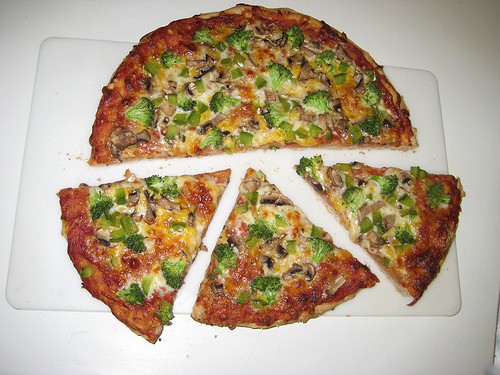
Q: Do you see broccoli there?
A: Yes, there is broccoli.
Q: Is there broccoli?
A: Yes, there is broccoli.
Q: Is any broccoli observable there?
A: Yes, there is broccoli.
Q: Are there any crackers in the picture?
A: No, there are no crackers.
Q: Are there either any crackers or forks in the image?
A: No, there are no crackers or forks.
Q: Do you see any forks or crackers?
A: No, there are no crackers or forks.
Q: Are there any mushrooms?
A: Yes, there are mushrooms.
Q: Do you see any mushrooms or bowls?
A: Yes, there are mushrooms.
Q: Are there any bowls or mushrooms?
A: Yes, there are mushrooms.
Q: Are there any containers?
A: No, there are no containers.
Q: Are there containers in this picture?
A: No, there are no containers.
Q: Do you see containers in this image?
A: No, there are no containers.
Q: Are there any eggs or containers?
A: No, there are no containers or eggs.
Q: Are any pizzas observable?
A: Yes, there is a pizza.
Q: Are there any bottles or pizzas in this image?
A: Yes, there is a pizza.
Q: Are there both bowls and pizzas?
A: No, there is a pizza but no bowls.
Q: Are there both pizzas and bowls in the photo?
A: No, there is a pizza but no bowls.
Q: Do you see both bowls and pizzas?
A: No, there is a pizza but no bowls.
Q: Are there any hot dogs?
A: No, there are no hot dogs.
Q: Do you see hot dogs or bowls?
A: No, there are no hot dogs or bowls.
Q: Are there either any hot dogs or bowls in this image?
A: No, there are no hot dogs or bowls.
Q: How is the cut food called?
A: The food is a pizza.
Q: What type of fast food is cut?
A: The fast food is a pizza.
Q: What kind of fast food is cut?
A: The fast food is a pizza.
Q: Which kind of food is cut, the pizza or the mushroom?
A: The pizza is cut.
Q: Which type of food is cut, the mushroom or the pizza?
A: The pizza is cut.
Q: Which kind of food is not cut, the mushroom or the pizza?
A: The mushroom is not cut.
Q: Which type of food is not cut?
A: The food is a mushroom.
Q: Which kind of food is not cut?
A: The food is a mushroom.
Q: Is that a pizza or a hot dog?
A: That is a pizza.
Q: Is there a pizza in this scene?
A: Yes, there is a pizza.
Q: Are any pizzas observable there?
A: Yes, there is a pizza.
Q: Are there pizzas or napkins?
A: Yes, there is a pizza.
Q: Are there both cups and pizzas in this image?
A: No, there is a pizza but no cups.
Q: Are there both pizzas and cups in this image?
A: No, there is a pizza but no cups.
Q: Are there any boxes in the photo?
A: No, there are no boxes.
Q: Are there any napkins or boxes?
A: No, there are no boxes or napkins.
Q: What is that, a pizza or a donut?
A: That is a pizza.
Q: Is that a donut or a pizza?
A: That is a pizza.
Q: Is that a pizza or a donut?
A: That is a pizza.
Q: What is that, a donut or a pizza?
A: That is a pizza.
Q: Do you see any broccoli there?
A: Yes, there is broccoli.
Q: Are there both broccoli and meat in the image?
A: No, there is broccoli but no meat.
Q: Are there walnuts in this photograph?
A: No, there are no walnuts.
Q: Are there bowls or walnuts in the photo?
A: No, there are no walnuts or bowls.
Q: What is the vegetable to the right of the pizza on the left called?
A: The vegetable is broccoli.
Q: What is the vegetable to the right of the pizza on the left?
A: The vegetable is broccoli.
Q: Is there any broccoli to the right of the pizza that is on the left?
A: Yes, there is broccoli to the right of the pizza.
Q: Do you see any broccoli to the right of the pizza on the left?
A: Yes, there is broccoli to the right of the pizza.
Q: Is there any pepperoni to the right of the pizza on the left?
A: No, there is broccoli to the right of the pizza.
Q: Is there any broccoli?
A: Yes, there is broccoli.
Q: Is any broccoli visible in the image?
A: Yes, there is broccoli.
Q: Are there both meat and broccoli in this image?
A: No, there is broccoli but no meat.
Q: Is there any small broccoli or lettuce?
A: Yes, there is small broccoli.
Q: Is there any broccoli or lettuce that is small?
A: Yes, the broccoli is small.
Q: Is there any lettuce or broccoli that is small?
A: Yes, the broccoli is small.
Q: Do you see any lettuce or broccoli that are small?
A: Yes, the broccoli is small.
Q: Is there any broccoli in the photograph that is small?
A: Yes, there is small broccoli.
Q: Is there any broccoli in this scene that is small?
A: Yes, there is broccoli that is small.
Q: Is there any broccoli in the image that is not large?
A: Yes, there is small broccoli.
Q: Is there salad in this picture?
A: No, there is no salad.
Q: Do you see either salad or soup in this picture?
A: No, there are no salad or soup.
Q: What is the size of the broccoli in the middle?
A: The broccoli is small.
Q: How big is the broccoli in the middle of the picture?
A: The broccoli is small.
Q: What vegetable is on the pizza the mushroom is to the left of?
A: The vegetable is broccoli.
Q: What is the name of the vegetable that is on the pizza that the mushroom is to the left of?
A: The vegetable is broccoli.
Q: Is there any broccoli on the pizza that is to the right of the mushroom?
A: Yes, there is broccoli on the pizza.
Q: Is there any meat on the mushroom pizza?
A: No, there is broccoli on the pizza.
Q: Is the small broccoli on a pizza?
A: Yes, the broccoli is on a pizza.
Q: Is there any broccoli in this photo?
A: Yes, there is broccoli.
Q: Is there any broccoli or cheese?
A: Yes, there is broccoli.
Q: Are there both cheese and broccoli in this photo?
A: Yes, there are both broccoli and cheese.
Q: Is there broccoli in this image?
A: Yes, there is broccoli.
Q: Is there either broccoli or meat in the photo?
A: Yes, there is broccoli.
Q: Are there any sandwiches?
A: No, there are no sandwiches.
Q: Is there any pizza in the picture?
A: Yes, there is a pizza.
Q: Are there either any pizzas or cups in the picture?
A: Yes, there is a pizza.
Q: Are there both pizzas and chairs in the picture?
A: No, there is a pizza but no chairs.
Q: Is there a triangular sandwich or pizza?
A: Yes, there is a triangular pizza.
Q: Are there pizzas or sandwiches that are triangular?
A: Yes, the pizza is triangular.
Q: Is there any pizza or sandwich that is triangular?
A: Yes, the pizza is triangular.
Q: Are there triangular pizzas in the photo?
A: Yes, there is a triangular pizza.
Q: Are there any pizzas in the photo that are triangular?
A: Yes, there is a pizza that is triangular.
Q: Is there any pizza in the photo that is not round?
A: Yes, there is a triangular pizza.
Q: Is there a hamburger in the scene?
A: No, there are no hamburgers.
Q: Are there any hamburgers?
A: No, there are no hamburgers.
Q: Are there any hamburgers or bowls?
A: No, there are no hamburgers or bowls.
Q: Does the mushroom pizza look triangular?
A: Yes, the pizza is triangular.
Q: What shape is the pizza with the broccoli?
A: The pizza is triangular.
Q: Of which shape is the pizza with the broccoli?
A: The pizza is triangular.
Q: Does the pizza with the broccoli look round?
A: No, the pizza is triangular.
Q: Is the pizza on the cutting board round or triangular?
A: The pizza is triangular.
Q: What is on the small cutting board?
A: The pizza is on the cutting board.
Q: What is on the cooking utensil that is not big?
A: The pizza is on the cutting board.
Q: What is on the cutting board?
A: The pizza is on the cutting board.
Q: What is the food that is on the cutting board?
A: The food is a pizza.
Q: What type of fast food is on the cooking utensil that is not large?
A: The food is a pizza.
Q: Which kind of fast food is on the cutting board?
A: The food is a pizza.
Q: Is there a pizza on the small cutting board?
A: Yes, there is a pizza on the cutting board.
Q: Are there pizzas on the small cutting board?
A: Yes, there is a pizza on the cutting board.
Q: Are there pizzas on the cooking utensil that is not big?
A: Yes, there is a pizza on the cutting board.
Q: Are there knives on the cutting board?
A: No, there is a pizza on the cutting board.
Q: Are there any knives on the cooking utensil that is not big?
A: No, there is a pizza on the cutting board.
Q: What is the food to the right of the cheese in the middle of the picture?
A: The food is a pizza.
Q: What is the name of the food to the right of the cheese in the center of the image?
A: The food is a pizza.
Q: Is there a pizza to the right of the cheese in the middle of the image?
A: Yes, there is a pizza to the right of the cheese.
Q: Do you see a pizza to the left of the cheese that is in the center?
A: No, the pizza is to the right of the cheese.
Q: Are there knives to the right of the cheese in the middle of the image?
A: No, there is a pizza to the right of the cheese.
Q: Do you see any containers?
A: No, there are no containers.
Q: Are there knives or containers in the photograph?
A: No, there are no containers or knives.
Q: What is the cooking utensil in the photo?
A: The cooking utensil is a cutting board.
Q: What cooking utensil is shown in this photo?
A: The cooking utensil is a cutting board.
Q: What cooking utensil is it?
A: The cooking utensil is a cutting board.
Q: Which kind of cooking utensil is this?
A: This is a cutting board.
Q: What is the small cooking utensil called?
A: The cooking utensil is a cutting board.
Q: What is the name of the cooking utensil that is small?
A: The cooking utensil is a cutting board.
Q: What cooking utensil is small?
A: The cooking utensil is a cutting board.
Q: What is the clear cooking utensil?
A: The cooking utensil is a cutting board.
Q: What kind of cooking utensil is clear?
A: The cooking utensil is a cutting board.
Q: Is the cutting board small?
A: Yes, the cutting board is small.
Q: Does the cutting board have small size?
A: Yes, the cutting board is small.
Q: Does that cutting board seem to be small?
A: Yes, the cutting board is small.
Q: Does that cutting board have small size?
A: Yes, the cutting board is small.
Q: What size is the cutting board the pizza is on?
A: The cutting board is small.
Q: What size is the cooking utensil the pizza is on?
A: The cutting board is small.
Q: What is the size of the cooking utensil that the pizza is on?
A: The cutting board is small.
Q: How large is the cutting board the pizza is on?
A: The cutting board is small.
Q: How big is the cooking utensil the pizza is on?
A: The cutting board is small.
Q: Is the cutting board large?
A: No, the cutting board is small.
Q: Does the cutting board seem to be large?
A: No, the cutting board is small.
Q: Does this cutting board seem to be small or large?
A: The cutting board is small.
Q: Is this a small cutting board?
A: Yes, this is a small cutting board.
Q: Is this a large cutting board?
A: No, this is a small cutting board.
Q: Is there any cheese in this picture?
A: Yes, there is cheese.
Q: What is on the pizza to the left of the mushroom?
A: The cheese is on the pizza.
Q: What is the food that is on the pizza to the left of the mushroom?
A: The food is cheese.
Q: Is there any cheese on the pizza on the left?
A: Yes, there is cheese on the pizza.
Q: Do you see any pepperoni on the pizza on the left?
A: No, there is cheese on the pizza.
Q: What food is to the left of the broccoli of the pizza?
A: The food is cheese.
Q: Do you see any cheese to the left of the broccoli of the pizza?
A: Yes, there is cheese to the left of the broccoli.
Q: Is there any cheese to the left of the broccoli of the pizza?
A: Yes, there is cheese to the left of the broccoli.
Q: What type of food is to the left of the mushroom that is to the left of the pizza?
A: The food is cheese.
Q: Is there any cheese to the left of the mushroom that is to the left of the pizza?
A: Yes, there is cheese to the left of the mushroom.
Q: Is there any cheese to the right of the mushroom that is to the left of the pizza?
A: No, the cheese is to the left of the mushroom.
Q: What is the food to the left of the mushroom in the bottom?
A: The food is cheese.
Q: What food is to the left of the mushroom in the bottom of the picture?
A: The food is cheese.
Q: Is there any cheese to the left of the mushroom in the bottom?
A: Yes, there is cheese to the left of the mushroom.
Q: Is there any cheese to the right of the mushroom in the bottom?
A: No, the cheese is to the left of the mushroom.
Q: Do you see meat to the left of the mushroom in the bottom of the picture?
A: No, there is cheese to the left of the mushroom.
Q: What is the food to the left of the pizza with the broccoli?
A: The food is cheese.